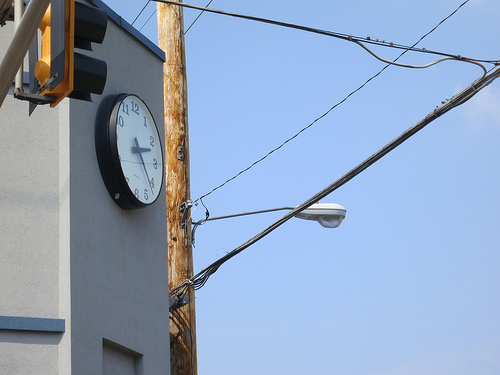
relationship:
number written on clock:
[147, 132, 156, 149] [92, 91, 164, 210]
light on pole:
[295, 202, 345, 227] [158, 3, 192, 373]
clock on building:
[100, 80, 177, 221] [10, 12, 237, 351]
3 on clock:
[151, 157, 160, 171] [92, 91, 164, 210]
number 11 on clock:
[120, 102, 129, 114] [92, 91, 164, 210]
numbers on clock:
[115, 92, 145, 119] [87, 89, 184, 214]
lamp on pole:
[199, 196, 353, 238] [152, 1, 204, 373]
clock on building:
[93, 84, 169, 213] [29, 172, 130, 301]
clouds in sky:
[372, 208, 477, 313] [103, 2, 497, 373]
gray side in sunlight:
[6, 110, 50, 317] [6, 1, 172, 373]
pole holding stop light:
[0, 0, 53, 116] [12, 1, 111, 112]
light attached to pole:
[295, 202, 345, 227] [149, 3, 208, 367]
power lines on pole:
[183, 2, 495, 259] [158, 3, 192, 373]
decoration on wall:
[73, 247, 137, 340] [83, 237, 149, 299]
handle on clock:
[127, 134, 156, 183] [90, 123, 154, 189]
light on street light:
[295, 202, 345, 227] [216, 185, 361, 258]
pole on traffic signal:
[5, 10, 35, 76] [32, 0, 111, 101]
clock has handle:
[93, 84, 169, 213] [127, 134, 156, 183]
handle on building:
[127, 134, 156, 183] [6, 1, 177, 374]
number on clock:
[125, 183, 140, 203] [97, 80, 162, 221]